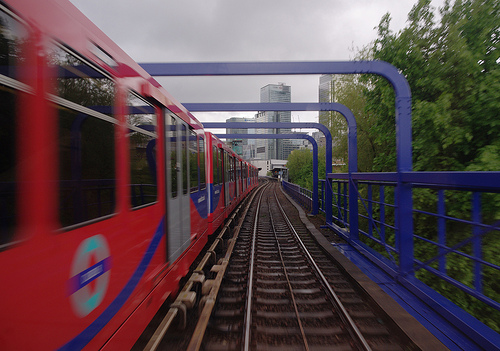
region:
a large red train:
[1, 0, 263, 347]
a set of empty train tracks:
[189, 162, 402, 348]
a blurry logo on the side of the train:
[67, 231, 115, 315]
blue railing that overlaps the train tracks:
[133, 55, 498, 350]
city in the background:
[211, 65, 365, 182]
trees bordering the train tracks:
[280, 2, 499, 317]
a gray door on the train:
[155, 108, 199, 260]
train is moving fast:
[2, 0, 262, 350]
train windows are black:
[1, 8, 262, 248]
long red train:
[3, 0, 272, 350]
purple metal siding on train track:
[140, 55, 497, 350]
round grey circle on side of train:
[57, 233, 121, 315]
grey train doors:
[160, 105, 202, 270]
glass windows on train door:
[167, 113, 194, 200]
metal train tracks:
[236, 179, 368, 349]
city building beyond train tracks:
[204, 70, 357, 180]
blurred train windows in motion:
[7, 15, 162, 267]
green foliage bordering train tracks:
[282, 16, 494, 335]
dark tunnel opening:
[264, 163, 289, 188]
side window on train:
[1, 7, 46, 233]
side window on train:
[51, 47, 128, 216]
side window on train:
[127, 85, 164, 225]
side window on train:
[190, 115, 207, 192]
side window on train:
[169, 100, 214, 194]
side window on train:
[196, 130, 218, 207]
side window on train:
[223, 142, 242, 187]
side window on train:
[234, 144, 245, 188]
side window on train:
[237, 153, 248, 178]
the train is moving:
[28, 45, 390, 346]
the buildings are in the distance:
[225, 73, 421, 251]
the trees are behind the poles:
[311, 68, 478, 162]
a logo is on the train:
[42, 254, 191, 338]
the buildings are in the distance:
[222, 92, 442, 265]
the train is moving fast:
[14, 24, 376, 262]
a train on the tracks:
[64, 31, 321, 329]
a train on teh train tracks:
[94, 113, 359, 350]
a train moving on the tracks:
[99, 78, 304, 283]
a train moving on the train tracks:
[132, 75, 302, 343]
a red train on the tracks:
[71, 83, 365, 346]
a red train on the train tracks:
[132, 95, 335, 344]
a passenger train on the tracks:
[100, 59, 339, 342]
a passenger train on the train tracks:
[91, 76, 373, 336]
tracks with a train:
[52, 77, 367, 347]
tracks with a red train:
[148, 154, 380, 339]